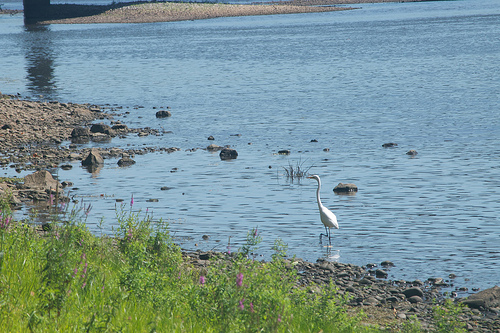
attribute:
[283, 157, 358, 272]
bird — standing, white, big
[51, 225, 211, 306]
grass — green, above, tall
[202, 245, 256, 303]
flower — purple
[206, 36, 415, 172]
water — still, reflected, large, blue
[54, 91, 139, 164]
rocks — brown, small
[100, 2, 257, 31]
ground — brown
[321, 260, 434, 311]
shore — rocky, here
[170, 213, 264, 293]
flowers — pink, purple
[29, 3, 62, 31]
beam — stone, supporting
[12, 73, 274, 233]
shoreline — rocks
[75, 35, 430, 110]
river — blue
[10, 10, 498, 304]
scene — daytime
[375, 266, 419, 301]
rock — gray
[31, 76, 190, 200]
beach — rocky